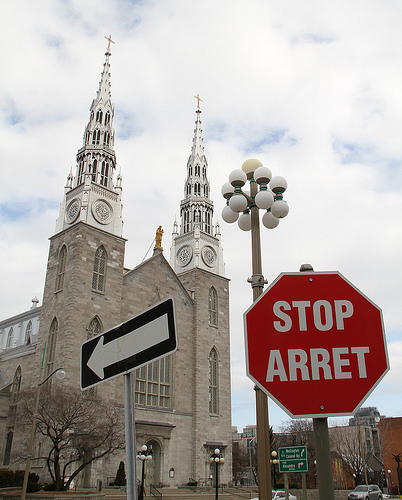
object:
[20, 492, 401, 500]
road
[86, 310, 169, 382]
arrow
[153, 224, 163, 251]
statue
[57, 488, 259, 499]
steps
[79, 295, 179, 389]
sign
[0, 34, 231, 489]
building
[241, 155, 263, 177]
lights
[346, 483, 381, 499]
car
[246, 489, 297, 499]
car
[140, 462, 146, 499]
pole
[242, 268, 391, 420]
red sign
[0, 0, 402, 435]
sky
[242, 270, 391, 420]
board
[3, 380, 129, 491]
tree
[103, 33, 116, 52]
cross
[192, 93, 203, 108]
cross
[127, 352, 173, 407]
window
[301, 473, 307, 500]
stand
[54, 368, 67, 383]
lamp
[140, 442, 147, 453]
lamp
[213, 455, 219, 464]
lamp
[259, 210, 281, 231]
light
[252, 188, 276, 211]
light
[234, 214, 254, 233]
light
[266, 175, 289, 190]
light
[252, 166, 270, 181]
light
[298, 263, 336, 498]
pole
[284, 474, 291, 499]
pole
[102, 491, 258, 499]
curb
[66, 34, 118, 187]
steeple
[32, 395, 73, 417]
leaves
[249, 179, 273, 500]
pole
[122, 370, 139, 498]
pole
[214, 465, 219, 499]
pole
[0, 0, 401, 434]
clouds